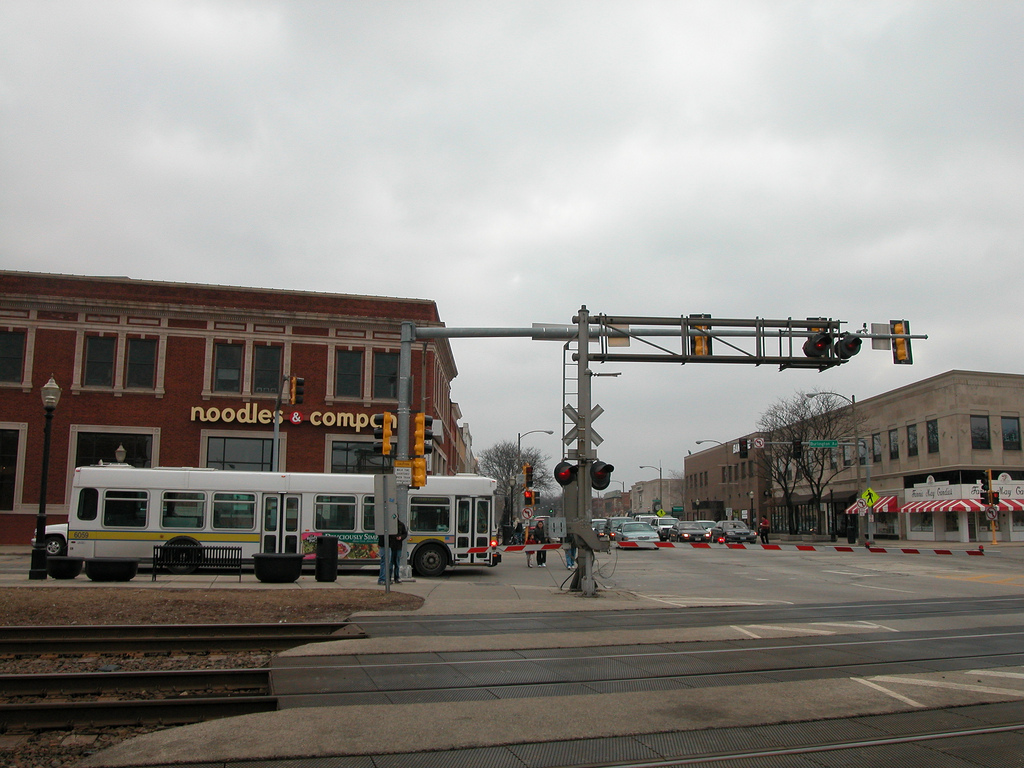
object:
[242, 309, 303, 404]
window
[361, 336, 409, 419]
window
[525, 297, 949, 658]
structure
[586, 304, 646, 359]
signs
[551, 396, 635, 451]
sign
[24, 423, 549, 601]
bus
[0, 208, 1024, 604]
building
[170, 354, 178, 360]
bricks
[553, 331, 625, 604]
pole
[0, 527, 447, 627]
sidewalk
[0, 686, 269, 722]
tracks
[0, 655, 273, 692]
tracks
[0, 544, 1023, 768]
ground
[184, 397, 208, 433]
lettering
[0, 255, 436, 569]
wall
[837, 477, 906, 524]
awning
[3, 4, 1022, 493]
sky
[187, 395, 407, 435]
sign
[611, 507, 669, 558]
cars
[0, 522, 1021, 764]
street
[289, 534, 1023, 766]
road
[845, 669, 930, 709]
lines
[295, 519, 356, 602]
trash can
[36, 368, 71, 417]
light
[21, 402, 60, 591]
pole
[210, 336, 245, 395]
window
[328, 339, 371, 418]
window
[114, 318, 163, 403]
window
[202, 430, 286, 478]
window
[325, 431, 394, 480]
window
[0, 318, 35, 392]
window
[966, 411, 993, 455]
window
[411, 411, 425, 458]
traffic light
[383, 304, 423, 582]
pole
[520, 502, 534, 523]
sign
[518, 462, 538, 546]
pole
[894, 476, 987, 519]
awning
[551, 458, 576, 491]
lights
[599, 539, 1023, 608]
crossing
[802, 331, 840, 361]
lights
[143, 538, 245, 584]
bench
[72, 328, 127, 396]
window